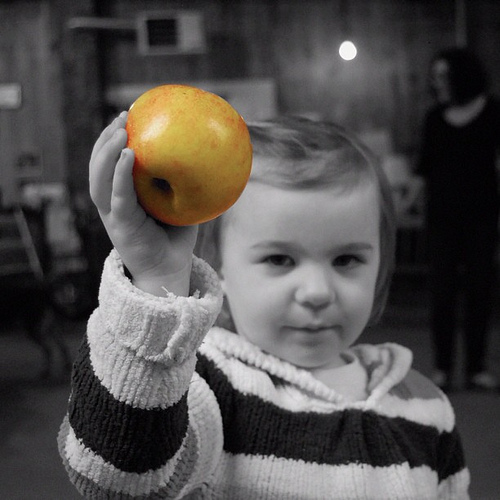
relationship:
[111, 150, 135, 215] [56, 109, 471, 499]
finger of child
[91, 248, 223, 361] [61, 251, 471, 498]
cuff of a sweater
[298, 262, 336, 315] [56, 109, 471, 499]
nose of a child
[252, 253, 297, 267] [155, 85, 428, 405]
eye of a girl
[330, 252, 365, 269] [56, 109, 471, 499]
eye of a child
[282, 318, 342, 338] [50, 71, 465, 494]
mouth of a child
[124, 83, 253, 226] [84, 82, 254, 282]
apple in hand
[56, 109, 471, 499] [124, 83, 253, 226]
child holding an apple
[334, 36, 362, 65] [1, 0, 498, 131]
light on back wall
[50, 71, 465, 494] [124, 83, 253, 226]
child holding an apple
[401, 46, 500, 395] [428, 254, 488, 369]
woman wearing pants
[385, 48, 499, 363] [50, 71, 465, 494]
woman standing behind child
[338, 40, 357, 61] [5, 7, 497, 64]
light hanging from a ceiling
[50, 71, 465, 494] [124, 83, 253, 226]
child posing with an apple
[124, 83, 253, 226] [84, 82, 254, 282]
apple held up in hand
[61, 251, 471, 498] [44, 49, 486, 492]
sweater worn by a child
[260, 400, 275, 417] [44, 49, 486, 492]
knitting worn by a child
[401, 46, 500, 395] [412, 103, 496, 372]
woman with clothes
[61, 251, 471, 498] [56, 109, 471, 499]
sweater worn by a child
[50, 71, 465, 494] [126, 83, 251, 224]
child holding onto an apple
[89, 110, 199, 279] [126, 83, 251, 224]
hand holding onto an apple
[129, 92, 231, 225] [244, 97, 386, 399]
apple held by child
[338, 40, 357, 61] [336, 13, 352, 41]
light attached to fixture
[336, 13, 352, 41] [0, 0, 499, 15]
fixture hanging from ceiling